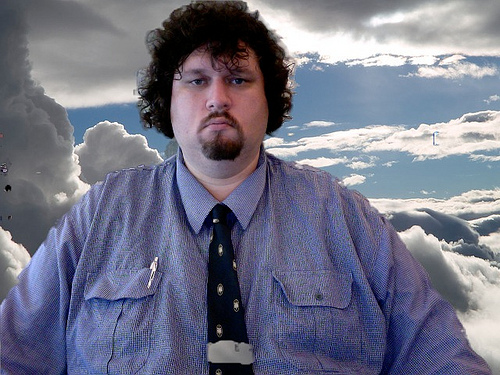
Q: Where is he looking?
A: At the camera.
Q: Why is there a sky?
A: Digital background.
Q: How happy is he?
A: Not happy.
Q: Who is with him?
A: No one.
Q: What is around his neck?
A: Tie.